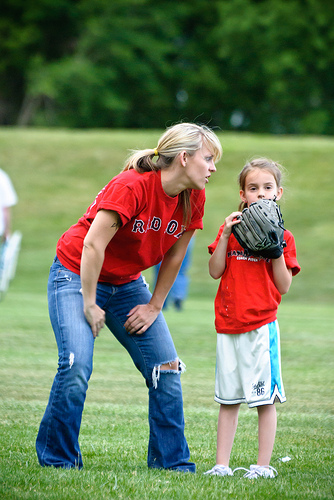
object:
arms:
[79, 186, 136, 311]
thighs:
[46, 260, 97, 367]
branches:
[0, 1, 333, 127]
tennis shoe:
[202, 465, 234, 475]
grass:
[0, 124, 333, 499]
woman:
[34, 121, 223, 476]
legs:
[36, 260, 100, 471]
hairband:
[152, 147, 158, 155]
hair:
[119, 121, 221, 173]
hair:
[235, 151, 285, 213]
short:
[213, 319, 286, 410]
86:
[255, 383, 266, 397]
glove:
[232, 196, 285, 261]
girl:
[203, 154, 301, 479]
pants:
[34, 250, 197, 473]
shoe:
[243, 459, 274, 480]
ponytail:
[119, 146, 158, 176]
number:
[255, 388, 261, 397]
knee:
[156, 349, 183, 376]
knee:
[63, 353, 94, 384]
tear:
[151, 353, 189, 389]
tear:
[67, 351, 74, 367]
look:
[249, 173, 275, 202]